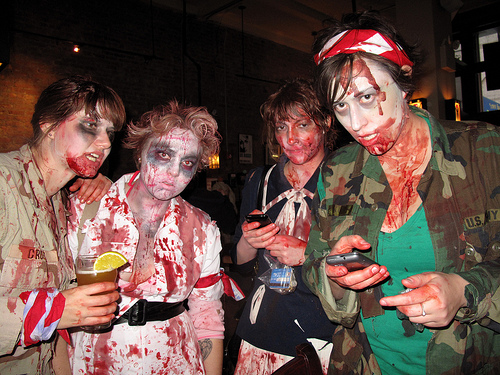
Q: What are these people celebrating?
A: Halloween.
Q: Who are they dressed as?
A: Zombies.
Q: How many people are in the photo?
A: Four.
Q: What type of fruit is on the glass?
A: Orange.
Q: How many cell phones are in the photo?
A: Two.